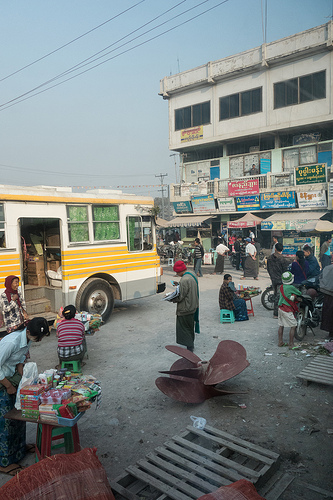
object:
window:
[172, 94, 209, 130]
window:
[219, 81, 265, 125]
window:
[271, 60, 327, 113]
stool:
[220, 308, 236, 324]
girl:
[219, 273, 250, 321]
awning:
[226, 211, 264, 229]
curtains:
[67, 205, 120, 243]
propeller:
[154, 339, 251, 404]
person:
[0, 274, 31, 363]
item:
[190, 413, 207, 430]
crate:
[105, 420, 279, 500]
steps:
[23, 285, 59, 323]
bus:
[0, 181, 167, 339]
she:
[0, 316, 51, 476]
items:
[14, 361, 103, 428]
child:
[278, 271, 302, 350]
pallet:
[107, 415, 280, 500]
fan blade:
[154, 339, 251, 404]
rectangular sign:
[297, 189, 327, 208]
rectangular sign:
[259, 190, 296, 209]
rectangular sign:
[236, 194, 260, 212]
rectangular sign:
[217, 197, 237, 212]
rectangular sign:
[190, 194, 216, 214]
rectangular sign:
[173, 200, 193, 214]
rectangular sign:
[293, 162, 328, 185]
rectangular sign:
[227, 179, 259, 198]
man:
[162, 257, 200, 355]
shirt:
[56, 318, 85, 359]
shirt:
[278, 284, 302, 306]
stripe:
[0, 245, 160, 291]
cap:
[173, 259, 187, 273]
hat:
[281, 271, 295, 285]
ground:
[0, 254, 333, 500]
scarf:
[4, 289, 21, 307]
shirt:
[0, 289, 28, 332]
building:
[157, 20, 333, 284]